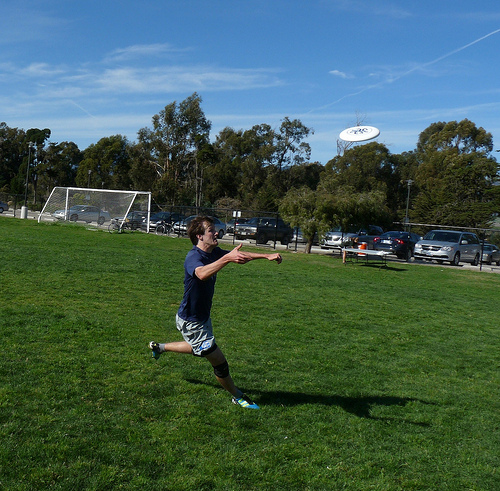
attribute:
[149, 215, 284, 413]
man — running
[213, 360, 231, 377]
brace — black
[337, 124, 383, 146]
frisbee — flying, white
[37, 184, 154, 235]
goal — large, white, backwards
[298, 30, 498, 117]
vapor trail — above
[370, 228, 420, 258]
car — parked, black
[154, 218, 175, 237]
bike — behind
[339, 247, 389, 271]
table — behind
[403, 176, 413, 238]
light — behind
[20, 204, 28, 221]
trash — behind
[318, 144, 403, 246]
tree — behind, green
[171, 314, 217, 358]
shorts — gray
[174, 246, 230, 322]
shirt — blue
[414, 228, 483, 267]
van — silver